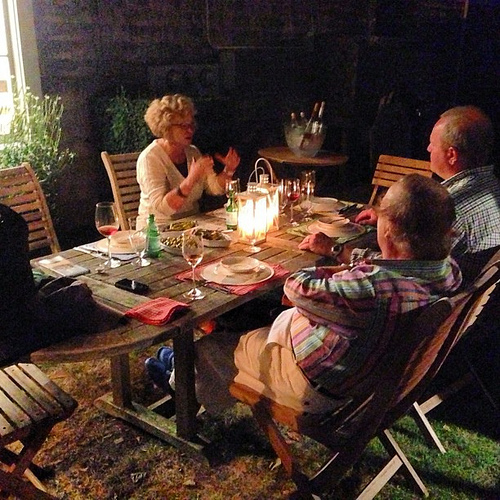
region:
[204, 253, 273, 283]
Plate on a table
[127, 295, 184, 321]
Red napkin on a table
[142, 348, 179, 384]
Blue shoes on a man's feet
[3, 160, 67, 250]
Chair with wooden slats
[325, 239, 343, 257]
Watch on a man's wrist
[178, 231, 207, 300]
Wine glass on a table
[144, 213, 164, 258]
Green bottle on a table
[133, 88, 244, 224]
woman at the table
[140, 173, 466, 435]
man in khaki pants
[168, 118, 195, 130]
glasses on a woman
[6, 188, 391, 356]
long wooden table top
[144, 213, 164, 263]
green bottle on the table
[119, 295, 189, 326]
unused red napkin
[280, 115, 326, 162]
bowl chilling wine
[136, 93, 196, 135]
woman's blonde hair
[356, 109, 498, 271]
man in a blue and white shirt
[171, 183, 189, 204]
watch on a woman's arm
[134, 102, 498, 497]
Three people sitting at an outdoor table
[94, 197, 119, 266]
wine glass on the table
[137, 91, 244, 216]
Woman gesturing with her hands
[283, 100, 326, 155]
Wine chilling in ice bucket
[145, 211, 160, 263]
glass bottle on the table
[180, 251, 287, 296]
Placemat under the plate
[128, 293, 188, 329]
Folded napkin on the table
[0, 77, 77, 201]
Flowering plant at the window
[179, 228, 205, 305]
Wine glass on the table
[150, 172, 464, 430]
Man wearing a plaid shirt and tan pants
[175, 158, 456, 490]
a man sitting at a table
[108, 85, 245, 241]
a woman sitting at a table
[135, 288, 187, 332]
a red cloth napkin